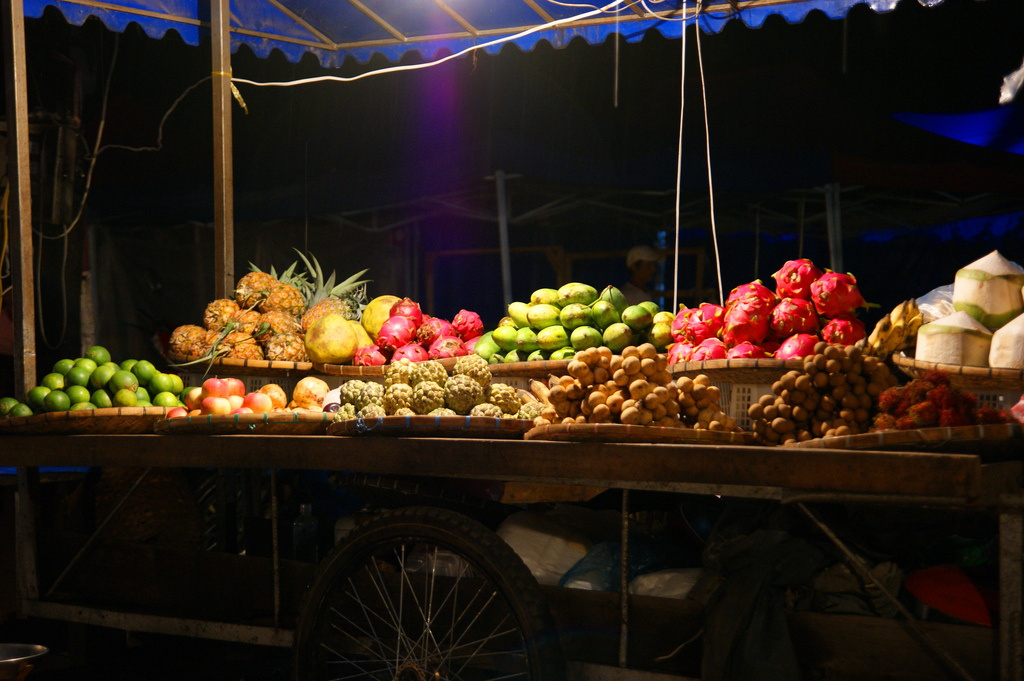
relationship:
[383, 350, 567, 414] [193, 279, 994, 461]
pineapple on stand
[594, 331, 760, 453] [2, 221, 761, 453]
potato on stand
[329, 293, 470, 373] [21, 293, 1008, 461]
cabbage on stand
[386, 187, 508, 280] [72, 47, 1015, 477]
wall on building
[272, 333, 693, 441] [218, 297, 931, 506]
fruit on counter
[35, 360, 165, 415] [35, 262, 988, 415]
pears on table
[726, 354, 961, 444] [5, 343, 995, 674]
potatoes on table